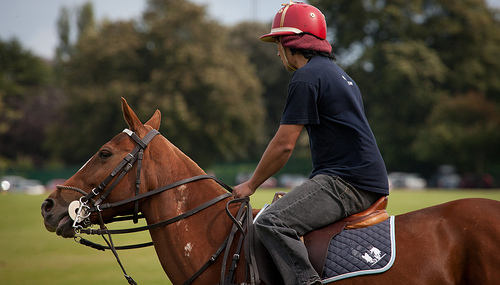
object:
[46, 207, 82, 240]
mouth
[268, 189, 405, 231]
saddle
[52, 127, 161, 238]
bridle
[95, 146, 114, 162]
eye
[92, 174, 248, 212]
reins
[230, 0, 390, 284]
man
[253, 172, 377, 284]
leg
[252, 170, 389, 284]
jeans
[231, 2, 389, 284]
guy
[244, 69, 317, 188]
arm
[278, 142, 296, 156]
elbow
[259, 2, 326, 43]
helmet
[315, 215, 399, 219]
blanket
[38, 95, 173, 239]
head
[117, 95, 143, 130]
ear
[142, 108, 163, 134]
ear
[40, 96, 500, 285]
horse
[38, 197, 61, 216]
nose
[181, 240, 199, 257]
spots